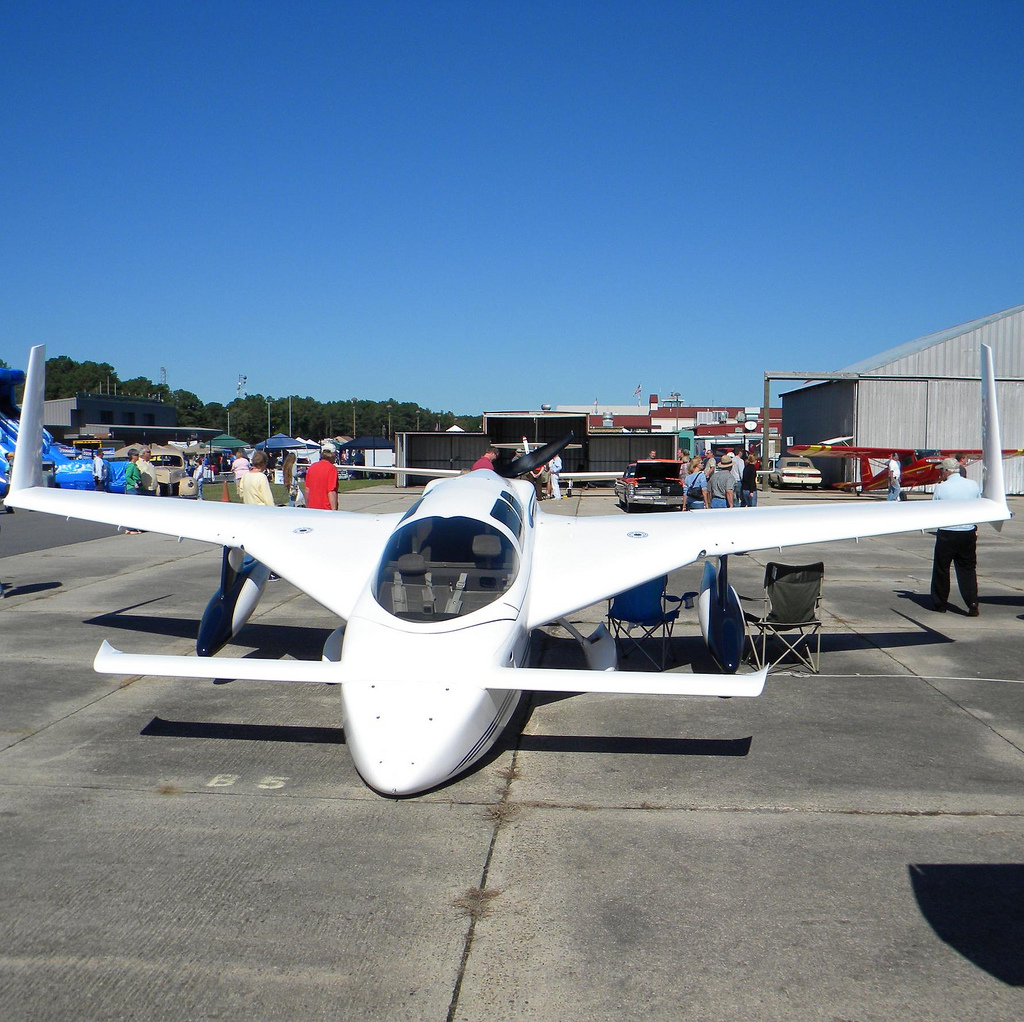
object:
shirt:
[306, 461, 338, 510]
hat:
[934, 458, 961, 474]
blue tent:
[255, 432, 321, 451]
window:
[370, 516, 521, 624]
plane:
[0, 338, 1015, 799]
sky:
[0, 0, 1024, 421]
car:
[613, 459, 687, 512]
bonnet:
[635, 476, 684, 495]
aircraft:
[788, 443, 1024, 490]